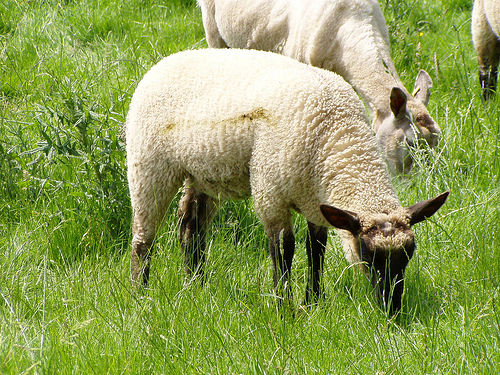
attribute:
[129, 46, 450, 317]
sheep — white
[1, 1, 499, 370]
grass — tall, green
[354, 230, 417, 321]
face — black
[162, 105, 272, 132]
stain — brown, dirty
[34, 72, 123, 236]
plant — green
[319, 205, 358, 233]
ear — black, pointed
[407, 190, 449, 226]
ear — black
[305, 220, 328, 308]
leg — black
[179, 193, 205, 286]
leg — black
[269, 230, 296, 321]
leg — black